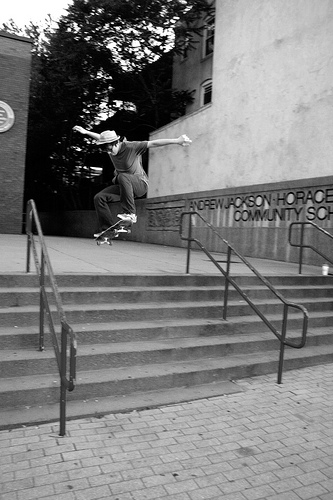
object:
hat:
[95, 129, 121, 144]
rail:
[179, 210, 309, 384]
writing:
[188, 187, 333, 222]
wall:
[0, 35, 32, 237]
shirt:
[108, 140, 150, 187]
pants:
[93, 172, 149, 231]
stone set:
[0, 234, 331, 276]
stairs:
[0, 273, 333, 294]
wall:
[146, 0, 333, 202]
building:
[0, 28, 35, 235]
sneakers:
[116, 212, 136, 224]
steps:
[1, 286, 333, 315]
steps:
[0, 299, 333, 338]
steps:
[0, 317, 333, 364]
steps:
[0, 335, 333, 396]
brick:
[267, 476, 304, 494]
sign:
[187, 184, 333, 230]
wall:
[37, 174, 333, 272]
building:
[146, 0, 333, 202]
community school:
[21, 0, 333, 275]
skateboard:
[94, 220, 134, 247]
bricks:
[197, 429, 227, 440]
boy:
[71, 125, 192, 246]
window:
[200, 77, 213, 108]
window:
[202, 10, 216, 59]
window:
[181, 32, 190, 65]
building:
[169, 1, 217, 123]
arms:
[133, 137, 179, 150]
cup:
[322, 265, 330, 275]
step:
[0, 368, 242, 429]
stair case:
[0, 274, 333, 431]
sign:
[0, 100, 15, 134]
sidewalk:
[0, 360, 333, 500]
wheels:
[113, 228, 117, 235]